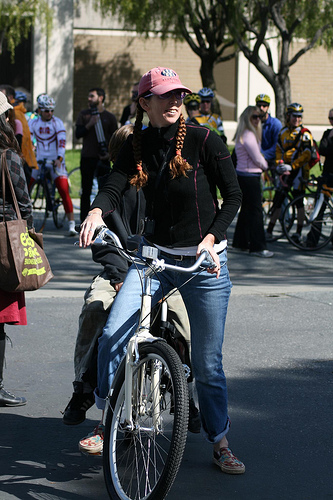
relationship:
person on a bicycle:
[74, 68, 244, 479] [75, 226, 211, 500]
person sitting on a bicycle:
[77, 65, 246, 475] [76, 226, 217, 499]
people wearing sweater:
[231, 104, 274, 258] [233, 130, 269, 175]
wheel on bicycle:
[102, 336, 191, 500] [75, 226, 211, 500]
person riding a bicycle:
[77, 65, 246, 475] [76, 226, 217, 499]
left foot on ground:
[213, 446, 243, 473] [10, 147, 332, 498]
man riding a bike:
[27, 92, 74, 234] [22, 157, 74, 233]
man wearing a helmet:
[27, 92, 74, 234] [35, 90, 58, 112]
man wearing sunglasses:
[27, 92, 74, 234] [40, 107, 54, 114]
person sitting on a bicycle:
[77, 65, 246, 475] [75, 226, 211, 500]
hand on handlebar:
[196, 235, 226, 278] [75, 222, 216, 274]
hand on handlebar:
[79, 208, 105, 247] [75, 222, 216, 274]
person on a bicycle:
[77, 65, 246, 475] [76, 226, 217, 499]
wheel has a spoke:
[102, 336, 191, 500] [141, 436, 155, 496]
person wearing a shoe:
[77, 65, 246, 475] [79, 431, 109, 456]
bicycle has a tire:
[76, 226, 217, 499] [102, 338, 189, 499]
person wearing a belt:
[77, 65, 246, 475] [145, 241, 227, 263]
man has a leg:
[27, 92, 74, 234] [52, 160, 75, 223]